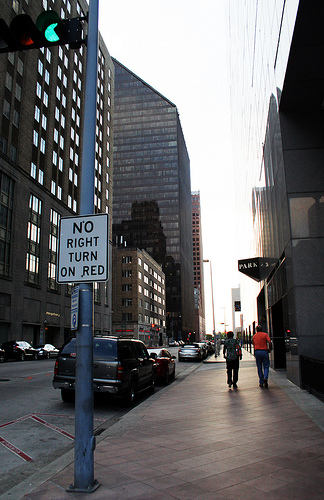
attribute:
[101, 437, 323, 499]
tiles — red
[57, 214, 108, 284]
sign — white, red, black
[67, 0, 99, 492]
pole — metal, grey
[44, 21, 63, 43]
light — green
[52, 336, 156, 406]
car — parked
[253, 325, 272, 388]
man — walking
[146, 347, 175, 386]
car — parked, red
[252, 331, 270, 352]
shirt — orange, red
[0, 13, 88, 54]
signal — green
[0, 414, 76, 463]
stripes — red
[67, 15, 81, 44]
bolts — silver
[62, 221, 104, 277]
letters — black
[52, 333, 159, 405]
suv — parked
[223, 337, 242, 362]
shirt — flowered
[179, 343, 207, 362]
car — silver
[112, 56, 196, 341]
sky scraper — black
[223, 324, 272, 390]
couple — walking